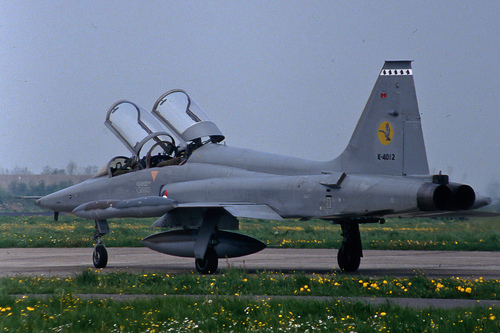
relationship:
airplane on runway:
[35, 55, 487, 285] [28, 242, 478, 281]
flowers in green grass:
[276, 274, 361, 292] [0, 267, 500, 298]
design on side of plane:
[367, 118, 397, 150] [37, 63, 478, 265]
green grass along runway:
[278, 272, 480, 324] [17, 227, 497, 281]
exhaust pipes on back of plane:
[409, 170, 483, 219] [29, 55, 499, 277]